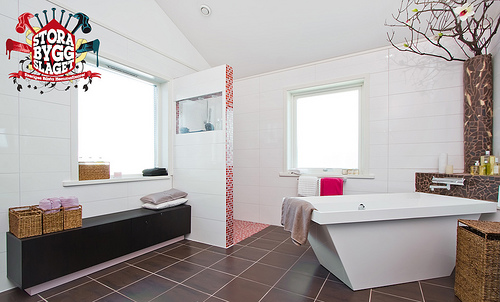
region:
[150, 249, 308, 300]
the floor is brown tile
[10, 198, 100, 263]
baskets on a ledge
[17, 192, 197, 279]
ledge is long and black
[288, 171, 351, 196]
towels are pink and white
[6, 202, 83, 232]
baskets are woven wicker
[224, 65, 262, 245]
shower has red and white tile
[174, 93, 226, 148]
shower has a window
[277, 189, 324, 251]
brown towel on tub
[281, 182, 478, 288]
tub is free standing.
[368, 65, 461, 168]
walls are white tile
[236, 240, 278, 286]
part of the floor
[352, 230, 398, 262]
surface of a bathtab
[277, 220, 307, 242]
part of a towel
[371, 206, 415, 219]
edge of a bathtab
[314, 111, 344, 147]
part of a window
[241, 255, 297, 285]
part of some lines on the floor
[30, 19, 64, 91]
part of a graphic writing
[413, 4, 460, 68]
part of some branches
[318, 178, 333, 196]
part of a pink towel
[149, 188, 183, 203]
part of some cushions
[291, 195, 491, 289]
A stand-alone soaker tub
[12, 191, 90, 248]
Baskets for storing towels on a bench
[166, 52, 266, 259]
A shower with red tiles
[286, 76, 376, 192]
A nice window in a bathroom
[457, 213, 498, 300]
A woven wood hamper for dirty clothes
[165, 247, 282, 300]
A brown tile bathroom floor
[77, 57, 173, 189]
A nice window above a bench.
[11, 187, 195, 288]
A bathroom storage bench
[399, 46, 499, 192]
A decorative bathroom display with a shelf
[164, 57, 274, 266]
An open bathroom shower with a window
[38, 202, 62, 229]
Wicker basket in the middle of the row of 3 on the black bench.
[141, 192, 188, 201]
Gray pillow on the black bench.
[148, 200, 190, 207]
White pillow on the black bench.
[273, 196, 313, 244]
Gray towel handing over the tub.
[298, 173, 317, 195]
White towel hanging below the window next to the pink towel.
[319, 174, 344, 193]
Pink towel hanging below the window next to the white one.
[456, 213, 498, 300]
Large wicker basket next to the tub.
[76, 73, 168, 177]
Large window next to the black bench.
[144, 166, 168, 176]
Black towels on the window sill of the large window.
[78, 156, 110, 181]
Wicker basket on the window sill.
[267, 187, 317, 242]
brown towel hanging off of bathtub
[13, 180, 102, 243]
3 square wicker baskets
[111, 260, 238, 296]
dark brown tile with tan grout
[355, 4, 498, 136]
brown plant with branches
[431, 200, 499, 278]
wicker laundry basket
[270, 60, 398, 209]
square window of bathroom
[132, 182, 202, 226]
brown and white towels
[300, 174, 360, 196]
red and white towel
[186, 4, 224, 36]
recess lighting on ceiling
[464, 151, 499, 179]
group of bathroom necessities